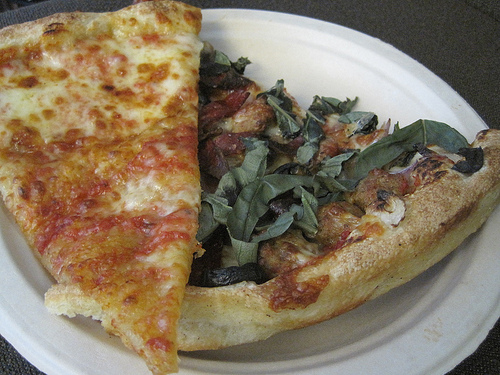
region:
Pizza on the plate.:
[11, 8, 493, 351]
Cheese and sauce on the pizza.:
[66, 78, 286, 298]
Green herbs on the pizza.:
[226, 95, 483, 319]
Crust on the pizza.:
[238, 229, 411, 346]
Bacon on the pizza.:
[215, 50, 427, 260]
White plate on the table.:
[277, 5, 459, 147]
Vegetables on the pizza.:
[203, 75, 439, 275]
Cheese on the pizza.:
[110, 93, 230, 283]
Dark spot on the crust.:
[264, 258, 371, 326]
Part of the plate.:
[370, 288, 462, 373]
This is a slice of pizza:
[45, 67, 189, 249]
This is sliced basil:
[269, 169, 341, 199]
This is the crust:
[253, 279, 318, 319]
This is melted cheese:
[125, 186, 160, 221]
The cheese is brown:
[60, 66, 228, 273]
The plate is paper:
[408, 329, 429, 354]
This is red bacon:
[200, 105, 248, 120]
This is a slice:
[75, 19, 164, 182]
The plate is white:
[298, 22, 343, 64]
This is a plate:
[368, 82, 405, 102]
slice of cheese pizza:
[1, 4, 201, 369]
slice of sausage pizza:
[177, 39, 493, 344]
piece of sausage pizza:
[201, 132, 243, 178]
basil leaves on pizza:
[214, 149, 312, 269]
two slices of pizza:
[1, 6, 499, 373]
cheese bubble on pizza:
[4, 123, 44, 155]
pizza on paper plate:
[0, 4, 498, 374]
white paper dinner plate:
[4, 8, 498, 372]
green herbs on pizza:
[199, 42, 470, 281]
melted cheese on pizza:
[120, 39, 193, 100]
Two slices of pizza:
[1, 31, 498, 344]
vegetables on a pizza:
[176, 56, 478, 274]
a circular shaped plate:
[0, 37, 495, 372]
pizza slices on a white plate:
[5, 75, 495, 369]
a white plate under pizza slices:
[1, 118, 498, 371]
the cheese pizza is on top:
[1, 41, 481, 358]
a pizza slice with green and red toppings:
[191, 55, 498, 347]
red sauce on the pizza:
[1, 37, 192, 373]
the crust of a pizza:
[2, 136, 497, 356]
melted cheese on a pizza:
[11, 57, 193, 344]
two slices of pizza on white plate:
[0, 2, 498, 372]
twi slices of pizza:
[0, 4, 497, 372]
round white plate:
[5, 5, 497, 372]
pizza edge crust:
[42, 124, 498, 353]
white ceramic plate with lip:
[0, 1, 496, 374]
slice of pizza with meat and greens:
[41, 35, 497, 353]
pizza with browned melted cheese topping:
[0, 0, 205, 373]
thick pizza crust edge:
[47, 130, 498, 357]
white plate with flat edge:
[0, 0, 498, 373]